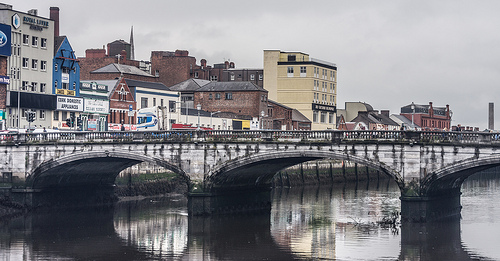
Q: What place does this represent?
A: It represents the city.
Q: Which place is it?
A: It is a city.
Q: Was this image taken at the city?
A: Yes, it was taken in the city.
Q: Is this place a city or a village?
A: It is a city.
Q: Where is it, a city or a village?
A: It is a city.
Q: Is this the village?
A: No, it is the city.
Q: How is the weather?
A: It is overcast.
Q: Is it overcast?
A: Yes, it is overcast.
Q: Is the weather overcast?
A: Yes, it is overcast.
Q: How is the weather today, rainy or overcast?
A: It is overcast.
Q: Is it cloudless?
A: No, it is overcast.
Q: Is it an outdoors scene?
A: Yes, it is outdoors.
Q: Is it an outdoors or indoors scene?
A: It is outdoors.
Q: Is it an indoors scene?
A: No, it is outdoors.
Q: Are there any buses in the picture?
A: No, there are no buses.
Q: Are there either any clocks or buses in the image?
A: No, there are no buses or clocks.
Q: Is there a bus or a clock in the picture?
A: No, there are no buses or clocks.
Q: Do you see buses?
A: No, there are no buses.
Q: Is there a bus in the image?
A: No, there are no buses.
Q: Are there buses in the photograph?
A: No, there are no buses.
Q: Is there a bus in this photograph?
A: No, there are no buses.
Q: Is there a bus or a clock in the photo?
A: No, there are no buses or clocks.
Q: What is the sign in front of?
A: The sign is in front of the building.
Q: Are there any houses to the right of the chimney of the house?
A: Yes, there is a house to the right of the chimney.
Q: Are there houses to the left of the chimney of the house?
A: No, the house is to the right of the chimney.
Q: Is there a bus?
A: No, there are no buses.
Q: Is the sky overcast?
A: Yes, the sky is overcast.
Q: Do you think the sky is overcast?
A: Yes, the sky is overcast.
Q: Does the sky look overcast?
A: Yes, the sky is overcast.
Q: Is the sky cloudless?
A: No, the sky is overcast.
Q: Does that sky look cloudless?
A: No, the sky is overcast.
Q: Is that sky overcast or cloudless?
A: The sky is overcast.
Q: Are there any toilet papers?
A: No, there are no toilet papers.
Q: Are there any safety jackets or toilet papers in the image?
A: No, there are no toilet papers or safety jackets.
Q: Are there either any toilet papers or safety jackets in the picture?
A: No, there are no toilet papers or safety jackets.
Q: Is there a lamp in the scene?
A: No, there are no lamps.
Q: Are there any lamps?
A: No, there are no lamps.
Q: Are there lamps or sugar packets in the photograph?
A: No, there are no lamps or sugar packets.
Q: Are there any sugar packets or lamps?
A: No, there are no lamps or sugar packets.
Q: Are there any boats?
A: No, there are no boats.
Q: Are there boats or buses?
A: No, there are no boats or buses.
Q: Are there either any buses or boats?
A: No, there are no boats or buses.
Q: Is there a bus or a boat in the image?
A: No, there are no boats or buses.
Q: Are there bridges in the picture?
A: Yes, there is a bridge.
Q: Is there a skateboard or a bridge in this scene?
A: Yes, there is a bridge.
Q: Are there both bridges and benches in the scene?
A: No, there is a bridge but no benches.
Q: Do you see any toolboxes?
A: No, there are no toolboxes.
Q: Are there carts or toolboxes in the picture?
A: No, there are no toolboxes or carts.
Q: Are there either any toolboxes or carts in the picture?
A: No, there are no toolboxes or carts.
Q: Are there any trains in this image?
A: No, there are no trains.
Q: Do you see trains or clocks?
A: No, there are no trains or clocks.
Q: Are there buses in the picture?
A: No, there are no buses.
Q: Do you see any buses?
A: No, there are no buses.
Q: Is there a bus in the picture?
A: No, there are no buses.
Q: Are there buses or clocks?
A: No, there are no buses or clocks.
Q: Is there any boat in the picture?
A: No, there are no boats.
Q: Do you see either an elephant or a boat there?
A: No, there are no boats or elephants.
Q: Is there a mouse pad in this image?
A: No, there are no mouse pads.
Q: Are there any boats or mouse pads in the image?
A: No, there are no mouse pads or boats.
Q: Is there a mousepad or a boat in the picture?
A: No, there are no mouse pads or boats.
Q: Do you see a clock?
A: No, there are no clocks.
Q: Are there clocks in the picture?
A: No, there are no clocks.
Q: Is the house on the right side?
A: Yes, the house is on the right of the image.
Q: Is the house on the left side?
A: No, the house is on the right of the image.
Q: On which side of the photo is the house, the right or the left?
A: The house is on the right of the image.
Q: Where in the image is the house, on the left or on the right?
A: The house is on the right of the image.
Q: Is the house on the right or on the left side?
A: The house is on the right of the image.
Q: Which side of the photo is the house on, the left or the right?
A: The house is on the right of the image.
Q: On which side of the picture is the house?
A: The house is on the right of the image.